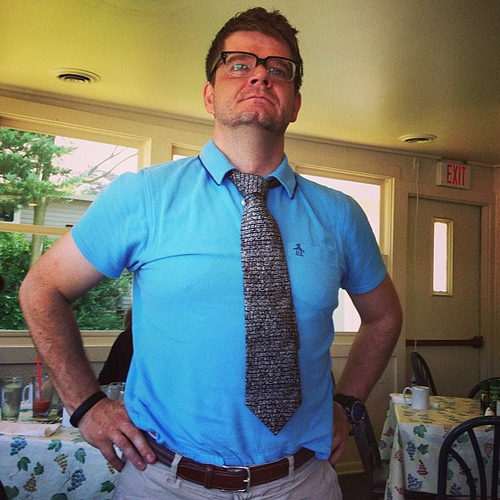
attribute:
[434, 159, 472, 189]
sign — exit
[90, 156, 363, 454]
blue shirt — Blue 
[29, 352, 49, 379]
straw — red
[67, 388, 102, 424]
bracelet — black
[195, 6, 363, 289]
man — Posing 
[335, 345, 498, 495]
chairs — green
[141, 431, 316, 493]
belt — brown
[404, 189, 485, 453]
door — cream colored